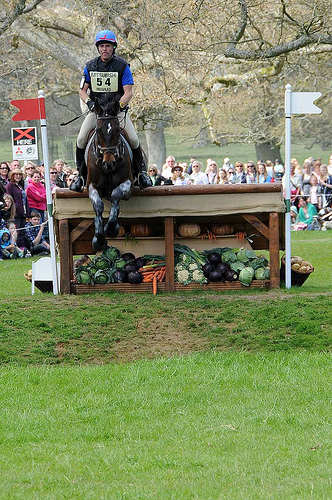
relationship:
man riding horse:
[69, 28, 155, 194] [76, 89, 136, 253]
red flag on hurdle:
[10, 91, 45, 123] [53, 184, 287, 296]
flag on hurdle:
[289, 92, 316, 114] [53, 184, 287, 296]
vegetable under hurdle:
[222, 248, 237, 263] [53, 184, 287, 296]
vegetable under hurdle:
[206, 248, 222, 265] [53, 184, 287, 296]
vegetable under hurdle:
[175, 265, 191, 283] [53, 184, 287, 296]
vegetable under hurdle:
[126, 268, 143, 283] [53, 184, 287, 296]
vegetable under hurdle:
[93, 266, 109, 284] [53, 184, 287, 296]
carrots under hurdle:
[140, 258, 171, 295] [53, 184, 287, 296]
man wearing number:
[72, 28, 154, 195] [95, 76, 113, 86]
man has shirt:
[69, 28, 155, 194] [106, 68, 137, 83]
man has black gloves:
[69, 28, 155, 194] [89, 97, 125, 116]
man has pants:
[69, 28, 155, 194] [112, 114, 140, 150]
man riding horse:
[69, 28, 155, 194] [84, 91, 131, 252]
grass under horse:
[0, 229, 330, 499] [74, 93, 145, 251]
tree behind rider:
[119, 0, 203, 179] [66, 32, 140, 125]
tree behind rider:
[0, 0, 86, 144] [66, 32, 140, 125]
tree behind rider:
[143, 25, 281, 146] [66, 32, 140, 125]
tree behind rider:
[222, 0, 330, 169] [66, 32, 140, 125]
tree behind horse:
[119, 0, 203, 179] [72, 107, 131, 232]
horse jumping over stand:
[83, 92, 134, 251] [53, 178, 286, 296]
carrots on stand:
[140, 258, 171, 295] [53, 178, 286, 296]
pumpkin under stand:
[211, 218, 235, 235] [53, 178, 286, 296]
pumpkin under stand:
[177, 223, 200, 236] [53, 178, 286, 296]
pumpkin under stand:
[130, 221, 150, 237] [53, 178, 286, 296]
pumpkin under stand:
[115, 224, 126, 236] [53, 178, 286, 296]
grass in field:
[0, 229, 330, 499] [0, 230, 331, 498]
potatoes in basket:
[285, 254, 312, 273] [281, 270, 312, 287]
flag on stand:
[289, 92, 321, 114] [280, 82, 295, 290]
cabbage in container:
[238, 267, 253, 286] [172, 206, 282, 286]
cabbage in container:
[254, 266, 272, 281] [172, 206, 282, 286]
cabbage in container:
[220, 247, 236, 262] [172, 206, 282, 286]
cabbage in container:
[235, 246, 254, 261] [172, 206, 282, 286]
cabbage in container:
[249, 258, 267, 269] [172, 206, 282, 286]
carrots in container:
[140, 258, 171, 295] [72, 281, 164, 290]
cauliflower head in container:
[191, 270, 200, 282] [164, 206, 308, 218]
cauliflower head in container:
[176, 268, 190, 283] [164, 206, 308, 218]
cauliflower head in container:
[188, 261, 196, 271] [164, 206, 308, 218]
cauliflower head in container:
[176, 261, 185, 270] [164, 206, 308, 218]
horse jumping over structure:
[79, 92, 134, 245] [52, 178, 284, 294]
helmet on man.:
[90, 27, 118, 49] [70, 26, 161, 159]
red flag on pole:
[10, 97, 46, 124] [35, 88, 58, 293]